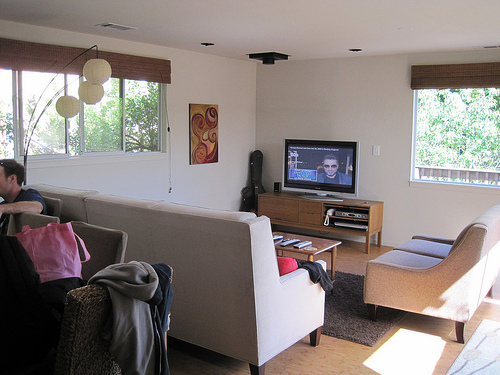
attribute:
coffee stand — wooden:
[274, 228, 342, 294]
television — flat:
[276, 130, 426, 208]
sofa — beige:
[38, 157, 348, 357]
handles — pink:
[15, 225, 93, 260]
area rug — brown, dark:
[318, 266, 398, 352]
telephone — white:
[317, 202, 342, 233]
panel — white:
[370, 145, 382, 157]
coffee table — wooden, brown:
[271, 231, 341, 299]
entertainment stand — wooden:
[252, 190, 382, 250]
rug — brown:
[320, 267, 399, 343]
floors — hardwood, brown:
[326, 240, 433, 373]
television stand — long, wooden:
[254, 190, 386, 250]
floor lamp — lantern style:
[46, 49, 111, 135]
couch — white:
[20, 179, 330, 373]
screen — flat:
[283, 135, 356, 193]